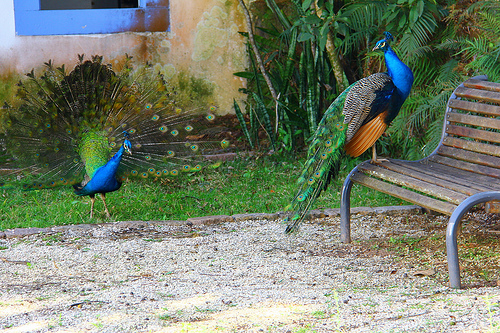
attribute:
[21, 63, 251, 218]
peacock — Male , tail feathers 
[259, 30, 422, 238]
peacock — tail feathers 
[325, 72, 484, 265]
bench — metal legs , wooden slats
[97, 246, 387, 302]
surface — gravel , Light 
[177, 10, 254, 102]
wall — Outdoor, algae stains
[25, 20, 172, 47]
frame — Blue outdoor window 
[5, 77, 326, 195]
plants — Tropical, outdoor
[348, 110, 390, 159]
feathers — Orange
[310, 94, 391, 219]
wing — peacock 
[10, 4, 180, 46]
window — Wood trimmed 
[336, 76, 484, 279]
bench — Wooden 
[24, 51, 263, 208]
peacock — tail open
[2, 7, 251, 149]
area — Grassy 